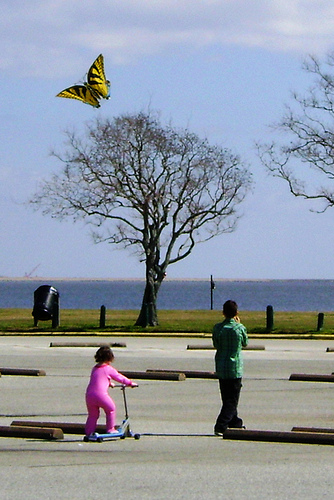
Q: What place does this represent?
A: It represents the parking lot.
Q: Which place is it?
A: It is a parking lot.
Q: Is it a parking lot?
A: Yes, it is a parking lot.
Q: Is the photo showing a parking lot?
A: Yes, it is showing a parking lot.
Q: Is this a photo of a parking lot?
A: Yes, it is showing a parking lot.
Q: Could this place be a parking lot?
A: Yes, it is a parking lot.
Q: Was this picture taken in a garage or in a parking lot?
A: It was taken at a parking lot.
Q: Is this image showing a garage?
A: No, the picture is showing a parking lot.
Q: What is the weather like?
A: It is cloudy.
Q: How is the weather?
A: It is cloudy.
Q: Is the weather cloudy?
A: Yes, it is cloudy.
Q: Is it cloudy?
A: Yes, it is cloudy.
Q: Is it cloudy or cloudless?
A: It is cloudy.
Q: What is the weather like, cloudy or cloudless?
A: It is cloudy.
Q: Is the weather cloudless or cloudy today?
A: It is cloudy.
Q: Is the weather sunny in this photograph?
A: No, it is cloudy.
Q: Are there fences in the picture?
A: No, there are no fences.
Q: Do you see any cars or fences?
A: No, there are no fences or cars.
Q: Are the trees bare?
A: Yes, the trees are bare.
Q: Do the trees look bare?
A: Yes, the trees are bare.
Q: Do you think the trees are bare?
A: Yes, the trees are bare.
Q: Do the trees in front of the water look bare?
A: Yes, the trees are bare.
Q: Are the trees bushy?
A: No, the trees are bare.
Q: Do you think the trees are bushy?
A: No, the trees are bare.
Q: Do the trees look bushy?
A: No, the trees are bare.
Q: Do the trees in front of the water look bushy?
A: No, the trees are bare.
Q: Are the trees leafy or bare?
A: The trees are bare.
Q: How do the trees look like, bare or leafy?
A: The trees are bare.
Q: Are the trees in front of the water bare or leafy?
A: The trees are bare.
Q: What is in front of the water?
A: The trees are in front of the water.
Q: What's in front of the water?
A: The trees are in front of the water.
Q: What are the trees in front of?
A: The trees are in front of the water.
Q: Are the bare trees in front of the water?
A: Yes, the trees are in front of the water.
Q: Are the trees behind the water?
A: No, the trees are in front of the water.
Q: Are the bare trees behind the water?
A: No, the trees are in front of the water.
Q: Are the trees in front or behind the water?
A: The trees are in front of the water.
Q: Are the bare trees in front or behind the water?
A: The trees are in front of the water.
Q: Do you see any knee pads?
A: No, there are no knee pads.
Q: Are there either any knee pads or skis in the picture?
A: No, there are no knee pads or skis.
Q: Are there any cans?
A: Yes, there is a can.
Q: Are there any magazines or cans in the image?
A: Yes, there is a can.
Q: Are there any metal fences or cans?
A: Yes, there is a metal can.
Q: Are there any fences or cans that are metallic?
A: Yes, the can is metallic.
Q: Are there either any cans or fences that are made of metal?
A: Yes, the can is made of metal.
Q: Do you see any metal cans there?
A: Yes, there is a metal can.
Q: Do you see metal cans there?
A: Yes, there is a metal can.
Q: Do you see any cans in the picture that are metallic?
A: Yes, there is a can that is metallic.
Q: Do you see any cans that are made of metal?
A: Yes, there is a can that is made of metal.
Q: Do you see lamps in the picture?
A: No, there are no lamps.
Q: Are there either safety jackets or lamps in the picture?
A: No, there are no lamps or safety jackets.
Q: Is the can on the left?
A: Yes, the can is on the left of the image.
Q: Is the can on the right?
A: No, the can is on the left of the image.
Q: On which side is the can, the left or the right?
A: The can is on the left of the image.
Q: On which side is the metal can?
A: The can is on the left of the image.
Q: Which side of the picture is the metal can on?
A: The can is on the left of the image.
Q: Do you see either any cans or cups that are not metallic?
A: No, there is a can but it is metallic.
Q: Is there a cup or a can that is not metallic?
A: No, there is a can but it is metallic.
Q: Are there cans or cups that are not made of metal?
A: No, there is a can but it is made of metal.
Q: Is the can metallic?
A: Yes, the can is metallic.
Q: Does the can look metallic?
A: Yes, the can is metallic.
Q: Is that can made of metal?
A: Yes, the can is made of metal.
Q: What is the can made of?
A: The can is made of metal.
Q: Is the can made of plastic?
A: No, the can is made of metal.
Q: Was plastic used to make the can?
A: No, the can is made of metal.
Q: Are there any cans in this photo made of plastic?
A: No, there is a can but it is made of metal.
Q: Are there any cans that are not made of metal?
A: No, there is a can but it is made of metal.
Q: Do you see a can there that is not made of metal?
A: No, there is a can but it is made of metal.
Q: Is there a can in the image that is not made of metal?
A: No, there is a can but it is made of metal.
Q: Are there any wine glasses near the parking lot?
A: No, there is a can near the parking lot.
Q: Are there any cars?
A: No, there are no cars.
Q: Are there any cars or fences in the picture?
A: No, there are no cars or fences.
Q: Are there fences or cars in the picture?
A: No, there are no cars or fences.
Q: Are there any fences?
A: No, there are no fences.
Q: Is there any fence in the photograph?
A: No, there are no fences.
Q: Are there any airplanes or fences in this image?
A: No, there are no fences or airplanes.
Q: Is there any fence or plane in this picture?
A: No, there are no fences or airplanes.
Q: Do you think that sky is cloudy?
A: Yes, the sky is cloudy.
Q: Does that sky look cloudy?
A: Yes, the sky is cloudy.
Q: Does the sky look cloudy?
A: Yes, the sky is cloudy.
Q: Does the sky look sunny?
A: No, the sky is cloudy.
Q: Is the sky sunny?
A: No, the sky is cloudy.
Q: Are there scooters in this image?
A: Yes, there is a scooter.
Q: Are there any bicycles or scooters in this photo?
A: Yes, there is a scooter.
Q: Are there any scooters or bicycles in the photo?
A: Yes, there is a scooter.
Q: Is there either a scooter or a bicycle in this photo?
A: Yes, there is a scooter.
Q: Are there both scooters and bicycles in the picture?
A: No, there is a scooter but no bikes.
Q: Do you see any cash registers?
A: No, there are no cash registers.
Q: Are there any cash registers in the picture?
A: No, there are no cash registers.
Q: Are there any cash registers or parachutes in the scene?
A: No, there are no cash registers or parachutes.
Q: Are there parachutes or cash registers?
A: No, there are no cash registers or parachutes.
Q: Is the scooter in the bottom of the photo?
A: Yes, the scooter is in the bottom of the image.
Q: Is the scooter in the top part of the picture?
A: No, the scooter is in the bottom of the image.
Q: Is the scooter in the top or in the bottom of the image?
A: The scooter is in the bottom of the image.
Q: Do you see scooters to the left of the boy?
A: Yes, there is a scooter to the left of the boy.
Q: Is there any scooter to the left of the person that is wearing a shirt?
A: Yes, there is a scooter to the left of the boy.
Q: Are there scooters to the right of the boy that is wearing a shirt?
A: No, the scooter is to the left of the boy.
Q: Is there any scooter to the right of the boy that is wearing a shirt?
A: No, the scooter is to the left of the boy.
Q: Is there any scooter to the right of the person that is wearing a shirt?
A: No, the scooter is to the left of the boy.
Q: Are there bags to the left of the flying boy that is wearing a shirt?
A: No, there is a scooter to the left of the boy.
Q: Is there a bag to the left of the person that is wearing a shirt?
A: No, there is a scooter to the left of the boy.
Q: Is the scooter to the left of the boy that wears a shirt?
A: Yes, the scooter is to the left of the boy.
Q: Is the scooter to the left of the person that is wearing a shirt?
A: Yes, the scooter is to the left of the boy.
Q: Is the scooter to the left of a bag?
A: No, the scooter is to the left of the boy.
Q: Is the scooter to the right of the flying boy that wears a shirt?
A: No, the scooter is to the left of the boy.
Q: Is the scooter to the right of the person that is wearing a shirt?
A: No, the scooter is to the left of the boy.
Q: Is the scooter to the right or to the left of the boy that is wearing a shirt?
A: The scooter is to the left of the boy.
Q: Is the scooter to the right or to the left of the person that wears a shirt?
A: The scooter is to the left of the boy.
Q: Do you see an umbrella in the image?
A: No, there are no umbrellas.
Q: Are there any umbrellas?
A: No, there are no umbrellas.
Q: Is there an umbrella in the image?
A: No, there are no umbrellas.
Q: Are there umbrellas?
A: No, there are no umbrellas.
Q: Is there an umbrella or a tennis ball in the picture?
A: No, there are no umbrellas or tennis balls.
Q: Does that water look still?
A: Yes, the water is still.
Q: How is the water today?
A: The water is still.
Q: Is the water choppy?
A: No, the water is still.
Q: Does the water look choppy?
A: No, the water is still.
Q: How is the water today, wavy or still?
A: The water is still.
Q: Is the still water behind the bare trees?
A: Yes, the water is behind the trees.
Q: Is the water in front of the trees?
A: No, the water is behind the trees.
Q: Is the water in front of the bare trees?
A: No, the water is behind the trees.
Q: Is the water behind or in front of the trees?
A: The water is behind the trees.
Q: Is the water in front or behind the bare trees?
A: The water is behind the trees.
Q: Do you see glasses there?
A: No, there are no glasses.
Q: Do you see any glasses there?
A: No, there are no glasses.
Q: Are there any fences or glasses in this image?
A: No, there are no glasses or fences.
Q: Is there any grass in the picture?
A: Yes, there is grass.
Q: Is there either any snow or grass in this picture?
A: Yes, there is grass.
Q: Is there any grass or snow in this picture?
A: Yes, there is grass.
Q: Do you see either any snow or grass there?
A: Yes, there is grass.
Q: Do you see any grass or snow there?
A: Yes, there is grass.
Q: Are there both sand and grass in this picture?
A: No, there is grass but no sand.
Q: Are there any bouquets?
A: No, there are no bouquets.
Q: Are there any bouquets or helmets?
A: No, there are no bouquets or helmets.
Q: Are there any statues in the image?
A: No, there are no statues.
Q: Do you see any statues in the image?
A: No, there are no statues.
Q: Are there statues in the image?
A: No, there are no statues.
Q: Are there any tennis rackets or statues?
A: No, there are no statues or tennis rackets.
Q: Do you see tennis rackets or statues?
A: No, there are no statues or tennis rackets.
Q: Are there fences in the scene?
A: No, there are no fences.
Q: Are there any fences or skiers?
A: No, there are no fences or skiers.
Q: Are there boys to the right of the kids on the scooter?
A: Yes, there is a boy to the right of the kids.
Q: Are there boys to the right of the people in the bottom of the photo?
A: Yes, there is a boy to the right of the kids.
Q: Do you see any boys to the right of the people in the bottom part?
A: Yes, there is a boy to the right of the kids.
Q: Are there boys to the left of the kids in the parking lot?
A: No, the boy is to the right of the children.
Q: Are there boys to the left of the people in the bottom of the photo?
A: No, the boy is to the right of the children.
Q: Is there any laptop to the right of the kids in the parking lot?
A: No, there is a boy to the right of the kids.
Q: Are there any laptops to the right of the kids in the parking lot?
A: No, there is a boy to the right of the kids.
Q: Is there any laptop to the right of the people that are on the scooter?
A: No, there is a boy to the right of the kids.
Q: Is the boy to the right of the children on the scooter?
A: Yes, the boy is to the right of the children.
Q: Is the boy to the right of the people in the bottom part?
A: Yes, the boy is to the right of the children.